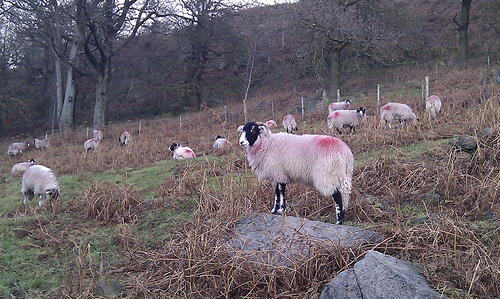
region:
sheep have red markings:
[275, 112, 375, 178]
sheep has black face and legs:
[213, 112, 381, 233]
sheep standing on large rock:
[181, 198, 470, 290]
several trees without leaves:
[13, 8, 193, 126]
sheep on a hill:
[296, 77, 469, 142]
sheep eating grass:
[16, 170, 71, 217]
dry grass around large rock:
[126, 180, 356, 290]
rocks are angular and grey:
[220, 192, 382, 296]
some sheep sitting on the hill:
[144, 114, 241, 174]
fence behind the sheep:
[147, 64, 488, 102]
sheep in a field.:
[8, 82, 457, 225]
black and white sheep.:
[0, 83, 452, 232]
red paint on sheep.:
[312, 130, 345, 157]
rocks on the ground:
[215, 202, 436, 291]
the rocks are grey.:
[216, 207, 436, 295]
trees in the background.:
[1, 0, 489, 130]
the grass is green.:
[8, 127, 471, 297]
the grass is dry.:
[0, 81, 495, 297]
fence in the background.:
[36, 56, 497, 154]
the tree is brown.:
[1, 1, 136, 143]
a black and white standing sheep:
[231, 115, 351, 217]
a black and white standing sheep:
[20, 161, 60, 208]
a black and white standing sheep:
[8, 154, 45, 180]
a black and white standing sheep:
[165, 141, 199, 158]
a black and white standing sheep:
[210, 130, 229, 149]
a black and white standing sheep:
[278, 110, 297, 132]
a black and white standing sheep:
[323, 105, 365, 127]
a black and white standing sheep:
[321, 90, 355, 113]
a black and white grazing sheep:
[373, 96, 419, 128]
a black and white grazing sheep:
[421, 90, 445, 117]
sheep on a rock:
[237, 115, 370, 237]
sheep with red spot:
[236, 113, 376, 227]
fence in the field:
[289, 83, 479, 110]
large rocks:
[220, 207, 404, 297]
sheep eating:
[12, 166, 67, 209]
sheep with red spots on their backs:
[318, 96, 463, 132]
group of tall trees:
[10, 23, 132, 135]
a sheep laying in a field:
[161, 135, 197, 166]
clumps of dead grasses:
[82, 176, 195, 291]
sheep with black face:
[232, 115, 280, 162]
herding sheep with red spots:
[8, 112, 432, 219]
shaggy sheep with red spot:
[234, 116, 374, 222]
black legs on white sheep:
[268, 178, 351, 235]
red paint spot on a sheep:
[308, 125, 341, 169]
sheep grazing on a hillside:
[151, 44, 468, 213]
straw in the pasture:
[176, 200, 399, 295]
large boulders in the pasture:
[189, 200, 426, 275]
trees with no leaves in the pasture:
[26, 10, 362, 90]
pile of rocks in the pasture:
[420, 125, 485, 221]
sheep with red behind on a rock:
[232, 113, 371, 222]